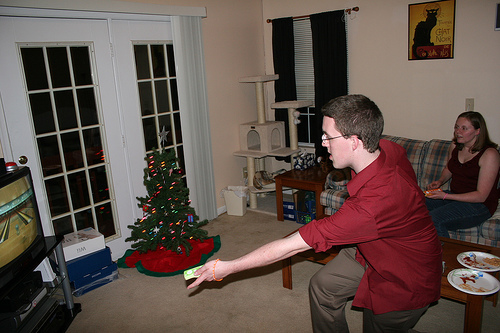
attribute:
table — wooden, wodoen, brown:
[301, 224, 495, 315]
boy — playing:
[233, 95, 439, 313]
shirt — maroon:
[305, 167, 447, 314]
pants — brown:
[312, 250, 395, 328]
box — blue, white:
[63, 241, 114, 272]